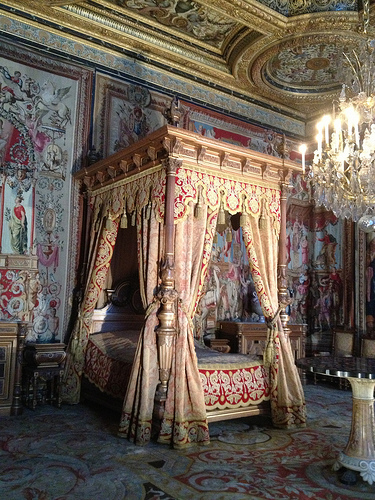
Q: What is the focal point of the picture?
A: Bed.